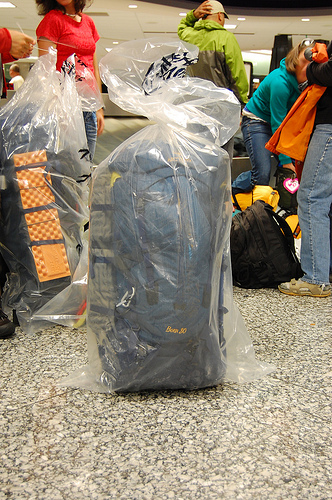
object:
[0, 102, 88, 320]
pack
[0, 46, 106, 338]
plastic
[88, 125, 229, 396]
bag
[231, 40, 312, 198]
traveler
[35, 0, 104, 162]
woman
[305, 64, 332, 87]
arm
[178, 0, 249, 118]
man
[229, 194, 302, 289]
backpack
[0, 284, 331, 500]
floor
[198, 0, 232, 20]
cap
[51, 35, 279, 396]
plastic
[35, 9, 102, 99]
shirt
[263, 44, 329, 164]
jacket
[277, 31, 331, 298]
person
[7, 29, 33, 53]
hands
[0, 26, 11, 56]
sleeves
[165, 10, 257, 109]
jacket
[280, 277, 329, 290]
socks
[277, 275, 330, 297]
sandals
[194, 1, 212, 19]
hand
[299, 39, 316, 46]
sunglasses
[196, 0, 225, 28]
head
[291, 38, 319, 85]
head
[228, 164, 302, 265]
luggage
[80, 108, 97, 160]
blue jeans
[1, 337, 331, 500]
tiles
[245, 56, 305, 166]
hoodie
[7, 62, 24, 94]
person